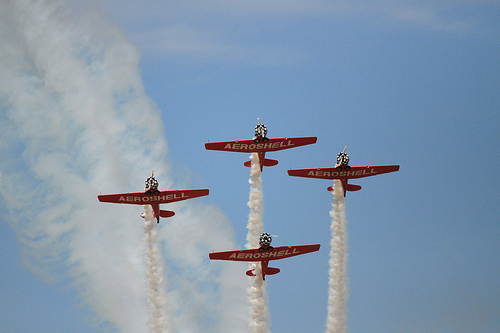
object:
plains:
[89, 103, 434, 314]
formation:
[64, 97, 411, 298]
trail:
[321, 174, 360, 333]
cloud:
[39, 232, 292, 333]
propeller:
[251, 115, 271, 142]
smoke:
[131, 198, 173, 333]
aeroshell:
[219, 136, 302, 155]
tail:
[243, 264, 284, 284]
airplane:
[203, 226, 327, 287]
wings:
[282, 164, 338, 182]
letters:
[370, 168, 378, 175]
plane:
[88, 169, 217, 231]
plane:
[281, 142, 410, 204]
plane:
[195, 112, 325, 176]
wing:
[205, 246, 263, 264]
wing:
[269, 242, 322, 264]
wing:
[158, 186, 212, 206]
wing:
[95, 191, 147, 208]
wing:
[200, 137, 259, 156]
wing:
[267, 134, 322, 153]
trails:
[239, 149, 274, 333]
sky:
[0, 0, 495, 333]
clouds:
[0, 0, 143, 132]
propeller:
[256, 229, 276, 252]